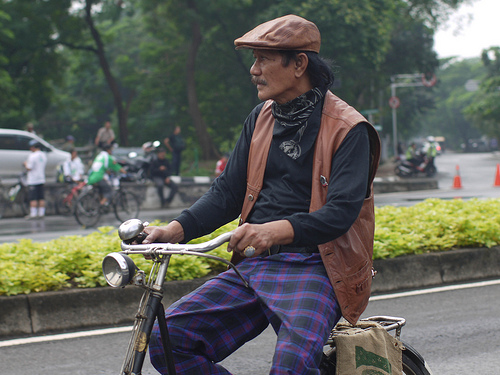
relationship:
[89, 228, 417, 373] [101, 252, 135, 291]
bike has a light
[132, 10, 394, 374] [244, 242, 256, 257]
man wearing ring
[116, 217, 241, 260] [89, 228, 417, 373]
handle bars are on front of bike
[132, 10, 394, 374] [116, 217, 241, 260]
man holding handle bars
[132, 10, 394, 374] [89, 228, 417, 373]
man riding bike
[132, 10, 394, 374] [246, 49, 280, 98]
man has face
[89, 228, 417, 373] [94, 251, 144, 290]
bike has headlight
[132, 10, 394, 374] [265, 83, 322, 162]
man wearing scarf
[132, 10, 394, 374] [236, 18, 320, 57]
man wearing cap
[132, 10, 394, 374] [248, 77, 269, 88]
man has a mustache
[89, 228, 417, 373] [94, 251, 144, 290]
bike has a headlight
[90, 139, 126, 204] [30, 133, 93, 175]
person riding bike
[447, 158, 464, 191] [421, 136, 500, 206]
cone in street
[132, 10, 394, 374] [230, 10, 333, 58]
man wearing hat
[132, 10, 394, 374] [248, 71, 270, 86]
man has moustache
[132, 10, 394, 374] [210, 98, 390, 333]
man wearing jacket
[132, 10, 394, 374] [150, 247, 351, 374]
man wearing pants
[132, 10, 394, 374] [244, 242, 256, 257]
man has ring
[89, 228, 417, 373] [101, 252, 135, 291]
bike has light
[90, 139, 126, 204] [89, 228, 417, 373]
person riding bike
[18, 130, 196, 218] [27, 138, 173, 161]
kids are wearing helmets